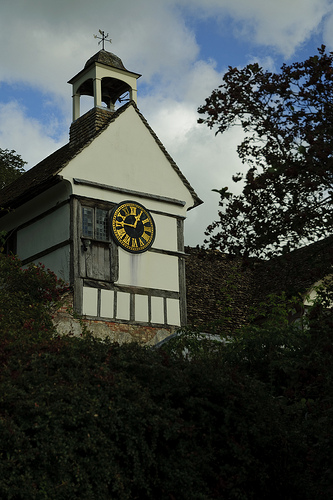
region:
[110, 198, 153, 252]
clock on the tower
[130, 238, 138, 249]
number on the clock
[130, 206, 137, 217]
number on the clock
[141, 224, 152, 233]
number on the clock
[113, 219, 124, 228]
number on the clock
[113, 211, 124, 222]
number on the clock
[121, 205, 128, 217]
number on the clock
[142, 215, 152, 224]
number on the clock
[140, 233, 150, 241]
number on the clock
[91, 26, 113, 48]
Dark metal weather vane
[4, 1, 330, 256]
Blue sky with many white and gray clouds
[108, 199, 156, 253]
Round clock with Roman numerals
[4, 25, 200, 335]
White building with brick roof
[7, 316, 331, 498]
Wall over grown with bushes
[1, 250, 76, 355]
Dark green bush with red flowers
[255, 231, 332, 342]
Arched dark brick opening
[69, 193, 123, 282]
Small window surrounded by wood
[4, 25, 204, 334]
Building with bell tower and clock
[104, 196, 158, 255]
Clock showing the time of 12:46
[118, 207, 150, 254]
clock's numbers are gold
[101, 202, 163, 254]
clock's numbers are gold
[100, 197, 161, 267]
a big clock on display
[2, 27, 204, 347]
White clock tower with cupola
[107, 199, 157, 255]
Round black clock face with gold numerals and hands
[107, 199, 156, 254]
Clock with roman numerals on white wall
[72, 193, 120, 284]
Window with many tiny panes next to clock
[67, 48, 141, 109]
Cupola on top of clock tower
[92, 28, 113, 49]
Weather vane on top of cupola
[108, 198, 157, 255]
Clock on wall showing time of 12:46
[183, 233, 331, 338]
Partially hidden roof of building supporting tower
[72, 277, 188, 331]
Rectangular section on wall framed with wood and containing vertical wood slats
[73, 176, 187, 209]
Horizontal wooden slat above clock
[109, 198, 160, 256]
clock on the building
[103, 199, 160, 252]
gold and black clock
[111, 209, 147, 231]
two gold clock hands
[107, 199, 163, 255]
gold roman numerals around the clock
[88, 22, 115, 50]
poles on top of the building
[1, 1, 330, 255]
white clouds in the sky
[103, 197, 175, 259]
clock indicating it's about 12:45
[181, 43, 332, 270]
top of a tree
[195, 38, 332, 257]
dark leaves on the tree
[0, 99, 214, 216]
roof is sloped